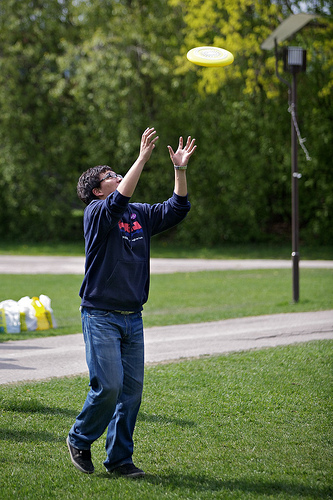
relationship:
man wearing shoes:
[53, 130, 217, 480] [44, 407, 190, 489]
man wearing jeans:
[65, 123, 199, 480] [60, 293, 156, 455]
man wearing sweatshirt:
[65, 123, 199, 480] [80, 190, 192, 311]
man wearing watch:
[65, 123, 199, 480] [170, 163, 189, 173]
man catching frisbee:
[65, 123, 199, 480] [185, 44, 235, 67]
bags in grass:
[2, 289, 61, 333] [0, 268, 329, 340]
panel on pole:
[257, 13, 315, 53] [292, 73, 302, 301]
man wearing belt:
[65, 123, 199, 480] [62, 287, 202, 320]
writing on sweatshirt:
[115, 218, 144, 230] [84, 196, 194, 306]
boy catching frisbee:
[63, 126, 196, 480] [175, 35, 245, 75]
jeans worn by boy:
[66, 305, 144, 465] [63, 126, 196, 480]